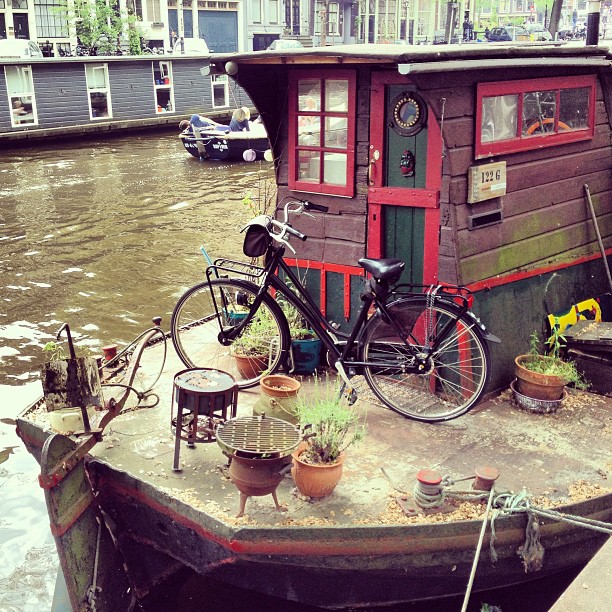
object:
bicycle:
[171, 196, 504, 424]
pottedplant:
[527, 317, 578, 384]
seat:
[357, 255, 404, 281]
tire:
[170, 278, 291, 391]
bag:
[239, 214, 272, 257]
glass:
[324, 116, 348, 149]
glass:
[323, 153, 347, 186]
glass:
[295, 149, 320, 183]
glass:
[210, 67, 228, 109]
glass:
[151, 60, 175, 114]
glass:
[83, 63, 113, 121]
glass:
[3, 64, 40, 128]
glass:
[35, 0, 66, 41]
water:
[0, 113, 319, 611]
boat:
[178, 105, 273, 162]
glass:
[297, 78, 323, 111]